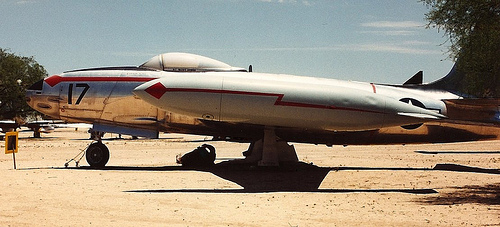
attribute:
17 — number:
[62, 76, 92, 108]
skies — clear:
[237, 11, 359, 76]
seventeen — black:
[61, 81, 86, 113]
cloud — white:
[350, 16, 429, 56]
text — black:
[65, 77, 87, 107]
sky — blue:
[0, 2, 496, 89]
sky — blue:
[90, 11, 376, 68]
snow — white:
[281, 47, 445, 58]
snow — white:
[363, 30, 435, 32]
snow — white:
[362, 20, 438, 28]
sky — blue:
[263, 25, 418, 45]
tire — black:
[83, 140, 110, 167]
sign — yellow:
[4, 127, 19, 153]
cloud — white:
[362, 18, 452, 35]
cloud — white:
[307, 39, 453, 62]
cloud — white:
[110, 45, 137, 62]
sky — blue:
[2, 0, 466, 79]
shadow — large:
[124, 157, 436, 202]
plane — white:
[15, 18, 499, 167]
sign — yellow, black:
[5, 129, 22, 170]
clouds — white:
[361, 22, 418, 59]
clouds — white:
[249, 9, 478, 89]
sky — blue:
[5, 1, 500, 133]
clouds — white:
[279, 9, 421, 64]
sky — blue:
[2, 3, 462, 91]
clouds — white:
[303, 8, 435, 53]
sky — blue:
[19, 7, 448, 46]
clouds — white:
[307, 10, 438, 69]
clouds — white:
[304, 24, 446, 60]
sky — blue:
[270, 11, 355, 61]